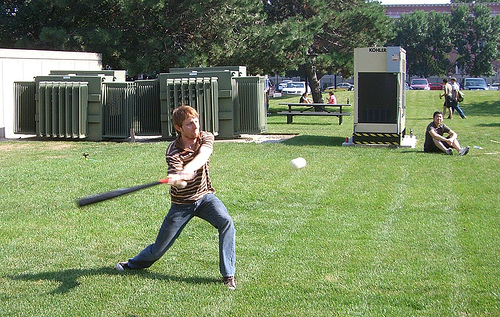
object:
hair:
[172, 105, 199, 128]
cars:
[326, 82, 355, 92]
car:
[281, 81, 312, 96]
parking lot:
[266, 78, 500, 99]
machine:
[34, 65, 267, 144]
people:
[299, 91, 337, 108]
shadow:
[0, 265, 230, 297]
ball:
[289, 157, 307, 169]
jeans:
[126, 193, 236, 278]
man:
[423, 110, 471, 156]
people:
[439, 78, 468, 121]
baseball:
[289, 157, 307, 170]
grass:
[356, 155, 436, 276]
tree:
[449, 3, 500, 79]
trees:
[0, 0, 267, 81]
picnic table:
[276, 102, 352, 125]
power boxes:
[353, 46, 408, 146]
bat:
[78, 178, 170, 207]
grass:
[1, 150, 150, 315]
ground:
[1, 91, 500, 317]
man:
[116, 105, 238, 291]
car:
[461, 77, 488, 91]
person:
[438, 78, 453, 120]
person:
[446, 77, 468, 121]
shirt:
[164, 130, 217, 204]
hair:
[433, 111, 444, 118]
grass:
[453, 162, 487, 267]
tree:
[248, 0, 395, 112]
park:
[0, 47, 499, 317]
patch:
[250, 223, 290, 255]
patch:
[388, 192, 406, 226]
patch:
[293, 254, 323, 277]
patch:
[46, 226, 66, 246]